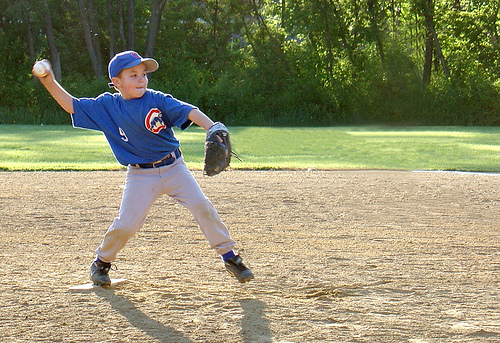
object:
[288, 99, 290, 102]
leaf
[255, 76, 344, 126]
plant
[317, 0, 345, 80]
tree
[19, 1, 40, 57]
woods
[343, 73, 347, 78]
leaf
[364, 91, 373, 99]
leaf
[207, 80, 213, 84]
leaf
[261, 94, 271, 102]
leaf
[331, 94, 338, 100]
leaf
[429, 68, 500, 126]
plant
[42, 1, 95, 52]
tree woods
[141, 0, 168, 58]
tree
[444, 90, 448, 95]
green leaf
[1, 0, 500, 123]
foliage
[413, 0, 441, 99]
tree